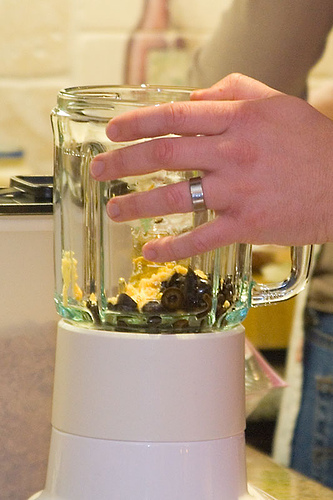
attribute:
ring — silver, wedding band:
[186, 175, 207, 215]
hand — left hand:
[88, 71, 333, 263]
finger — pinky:
[141, 218, 230, 263]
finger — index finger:
[104, 100, 231, 144]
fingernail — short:
[106, 123, 120, 139]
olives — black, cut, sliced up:
[96, 271, 240, 334]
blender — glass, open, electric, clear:
[46, 86, 315, 334]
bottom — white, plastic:
[42, 319, 248, 500]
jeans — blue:
[289, 303, 333, 489]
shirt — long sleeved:
[184, 1, 332, 312]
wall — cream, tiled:
[1, 3, 128, 88]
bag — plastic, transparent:
[246, 334, 291, 426]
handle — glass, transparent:
[251, 244, 315, 308]